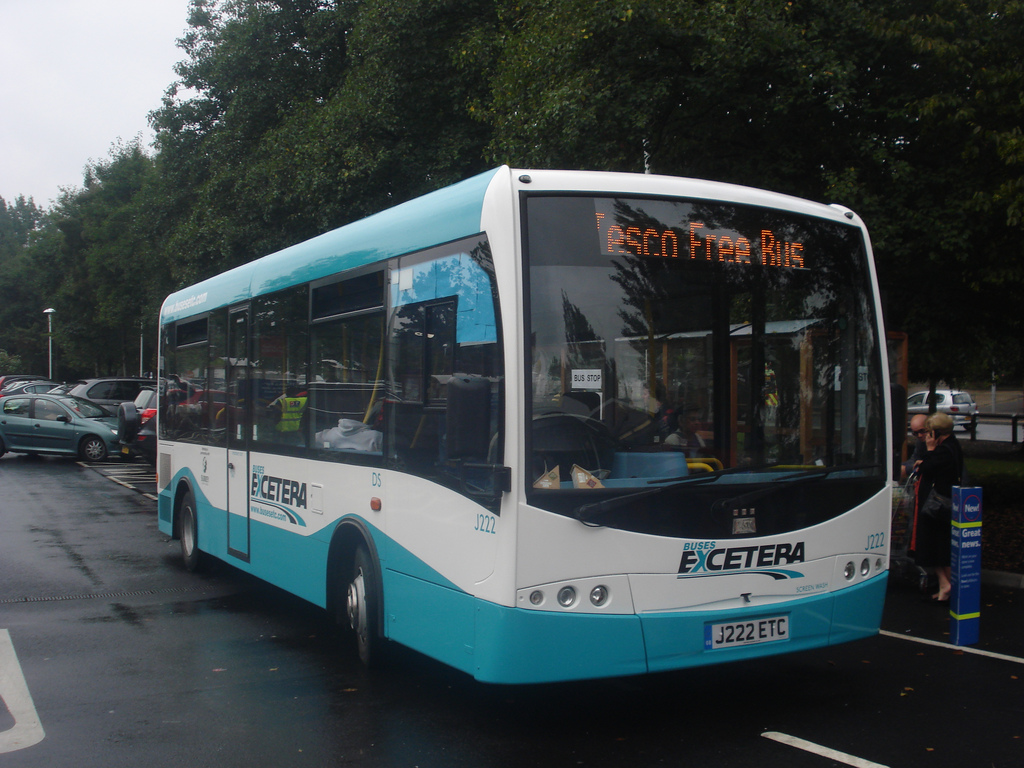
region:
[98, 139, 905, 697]
blue and white transit bus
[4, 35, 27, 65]
white clouds in blue sky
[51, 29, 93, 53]
white clouds in blue sky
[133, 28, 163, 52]
white clouds in blue sky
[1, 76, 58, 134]
white clouds in blue sky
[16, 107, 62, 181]
white clouds in blue sky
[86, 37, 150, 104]
white clouds in blue sky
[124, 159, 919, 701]
The blue bus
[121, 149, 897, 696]
A blue bus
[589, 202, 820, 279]
The digital display on the bus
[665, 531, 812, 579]
The name of the bus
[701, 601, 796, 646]
The license plate on the bus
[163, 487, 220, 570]
The rear tire of the bus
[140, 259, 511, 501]
The row of windows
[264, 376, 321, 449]
The person in the reflection on the bus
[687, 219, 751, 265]
The orange word Free.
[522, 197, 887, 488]
Front windshield of a bus.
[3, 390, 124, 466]
A green car behind a bus.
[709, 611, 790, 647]
A white rectangle license plate with black letters and numbers.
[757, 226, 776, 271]
Orange letter B on a bus windshield.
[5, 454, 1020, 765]
A black paved road with white lines.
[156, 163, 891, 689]
A blue and white bus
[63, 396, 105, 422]
Front windshield on a green car.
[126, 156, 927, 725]
the bus is white and blue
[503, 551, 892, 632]
front lights on the bus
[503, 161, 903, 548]
windshield of a bus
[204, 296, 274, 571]
the door of a bus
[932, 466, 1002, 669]
the pole is color blue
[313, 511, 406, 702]
the front wheel of the bus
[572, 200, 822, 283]
letters on top the bus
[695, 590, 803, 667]
plate on the front of bus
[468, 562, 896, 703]
the bumper is blue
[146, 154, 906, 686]
teal and white passenger bus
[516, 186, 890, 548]
large clear glass windshield of a bus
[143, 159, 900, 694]
blue and white bus in street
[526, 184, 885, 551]
dark windshield in front of big blue and white bus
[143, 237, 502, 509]
dark window in right side of bus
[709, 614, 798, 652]
white license plate with black letters and numbers